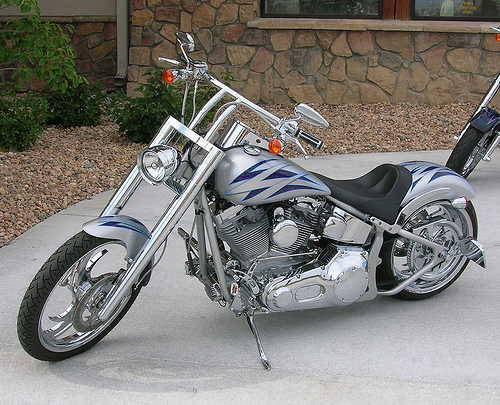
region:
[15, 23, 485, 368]
the silver and blue motorcycle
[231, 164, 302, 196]
the blue designs on the bikes frame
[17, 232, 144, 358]
the motorcycle's front wheel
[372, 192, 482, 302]
the motorcycle's back wheel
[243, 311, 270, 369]
the metal kick stand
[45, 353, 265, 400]
the shadow from the wheel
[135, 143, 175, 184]
the front white light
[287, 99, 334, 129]
the left hand mirror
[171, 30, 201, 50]
the right hand mirror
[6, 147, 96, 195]
the rocks on the ground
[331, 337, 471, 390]
The ground is gray.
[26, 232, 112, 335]
The tire is black.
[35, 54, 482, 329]
A motorcycle is in the picture.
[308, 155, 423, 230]
The seat is black.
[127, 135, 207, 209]
The motorcycle has a headlight.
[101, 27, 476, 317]
The motorcycle is not being used.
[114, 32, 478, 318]
The motorcycle is glossy.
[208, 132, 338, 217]
The gas tank is gray.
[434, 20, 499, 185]
Another bike is in the background.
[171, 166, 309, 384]
The bike is propped up.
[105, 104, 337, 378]
a motorbike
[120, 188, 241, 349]
a motorbike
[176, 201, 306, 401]
a motorbike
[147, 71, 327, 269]
a motorbike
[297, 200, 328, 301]
a motorbike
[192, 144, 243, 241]
a motorbike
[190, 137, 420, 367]
a motorbike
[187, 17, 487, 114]
House is made of stone.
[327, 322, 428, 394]
The driveway is grey.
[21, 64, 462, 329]
Bike in the driveway.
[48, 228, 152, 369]
The tire is black.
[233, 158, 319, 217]
Blue on the bike.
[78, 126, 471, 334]
The bike is silver.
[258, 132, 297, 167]
The light is orange.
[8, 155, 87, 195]
Stone next to the driveway.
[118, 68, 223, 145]
The plant is green.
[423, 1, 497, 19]
Sign in the window.